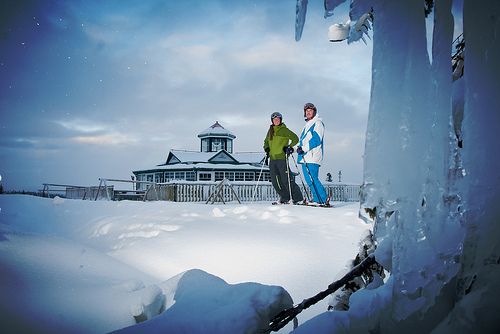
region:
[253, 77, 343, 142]
face of the persons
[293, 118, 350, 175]
a man wearing jacket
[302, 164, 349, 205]
a man wearing pant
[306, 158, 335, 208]
a man wearing blue pant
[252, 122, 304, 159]
a woman wearing jacket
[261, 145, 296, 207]
a woman wearing jeans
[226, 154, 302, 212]
a girl holding stick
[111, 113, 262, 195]
a beautiful building in the back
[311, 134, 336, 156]
blue lines in the shirt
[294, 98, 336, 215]
person in a blue and white snowsuit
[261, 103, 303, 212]
person wearing green and grey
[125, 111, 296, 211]
building in the back of people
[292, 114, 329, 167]
blue and white snow jacket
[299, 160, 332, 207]
blue snow pants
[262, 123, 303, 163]
light green snow jacket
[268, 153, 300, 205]
grey colored snow pants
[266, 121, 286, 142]
brown scarf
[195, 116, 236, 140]
top roof on the building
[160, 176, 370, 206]
fence around a building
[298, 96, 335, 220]
woman standingn on ski slope holding ski poles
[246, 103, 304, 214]
older woman standing on ski slope holding ski poles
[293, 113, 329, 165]
woman wearing white jacket with blue inserts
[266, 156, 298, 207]
woman wearing grey ski pants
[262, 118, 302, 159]
woman wearing green coat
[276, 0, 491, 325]
ice formation on tree in foreground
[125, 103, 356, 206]
large white ski lodge with snow on tower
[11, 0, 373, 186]
blue sky with heavy white winter clouds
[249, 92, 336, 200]
people are standing in the snow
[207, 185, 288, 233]
tracks in the snow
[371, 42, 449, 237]
ice hanging from the tree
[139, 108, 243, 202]
house behind the people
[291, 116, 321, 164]
person is wearing a blue and white coat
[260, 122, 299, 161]
person is wearing a green coat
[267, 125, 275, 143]
person has long hair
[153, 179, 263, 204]
fence around the house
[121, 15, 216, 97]
clouds fill the sky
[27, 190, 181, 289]
snow covers the ground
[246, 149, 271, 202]
a person holding a ski pole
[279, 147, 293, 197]
a person holding a ski pole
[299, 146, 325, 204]
a man holding a ski pole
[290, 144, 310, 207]
a man holding a ski pole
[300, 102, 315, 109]
a man with snow goggles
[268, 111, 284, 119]
a person with snow goggles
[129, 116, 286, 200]
a large house in the snow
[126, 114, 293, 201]
a large house covered in snow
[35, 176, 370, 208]
a long wooden fence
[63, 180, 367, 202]
a long wooden fence covered with snow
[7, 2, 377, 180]
the cloudy sky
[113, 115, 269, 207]
the house in the background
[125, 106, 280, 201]
A house in the background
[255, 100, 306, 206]
The person to the left on the snow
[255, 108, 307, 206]
A person to the left on the snow